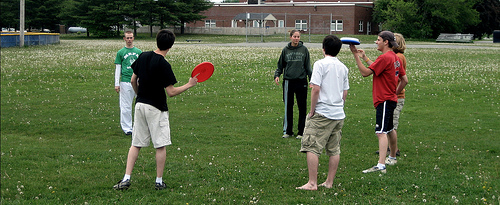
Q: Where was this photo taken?
A: The park.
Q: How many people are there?
A: Six.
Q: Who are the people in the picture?
A: Students.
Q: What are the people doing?
A: Playing frisbee.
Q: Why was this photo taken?
A: For a magazine.